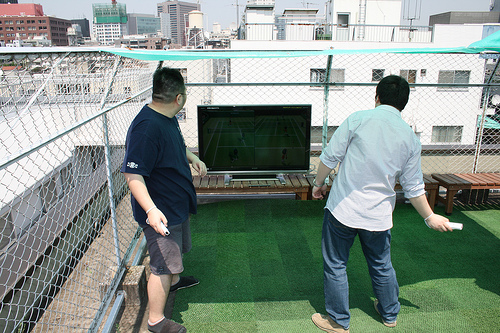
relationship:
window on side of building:
[310, 69, 350, 92] [125, 43, 498, 156]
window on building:
[434, 69, 473, 92] [125, 43, 498, 156]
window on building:
[310, 69, 350, 92] [125, 43, 498, 156]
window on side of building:
[216, 56, 230, 80] [125, 43, 498, 156]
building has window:
[125, 43, 498, 156] [310, 69, 350, 92]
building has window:
[125, 43, 498, 156] [216, 56, 230, 80]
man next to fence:
[117, 66, 213, 332] [15, 70, 163, 323]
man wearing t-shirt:
[117, 66, 213, 332] [129, 128, 199, 227]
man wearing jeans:
[316, 87, 453, 330] [322, 225, 404, 320]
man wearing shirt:
[316, 87, 453, 330] [334, 115, 426, 224]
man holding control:
[316, 87, 453, 330] [427, 217, 468, 236]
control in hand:
[427, 217, 468, 236] [432, 210, 451, 236]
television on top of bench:
[185, 99, 321, 176] [190, 172, 311, 202]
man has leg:
[117, 66, 213, 332] [146, 268, 177, 333]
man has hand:
[316, 87, 453, 330] [432, 210, 451, 236]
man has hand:
[117, 66, 213, 332] [145, 211, 177, 231]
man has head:
[117, 66, 213, 332] [146, 70, 193, 108]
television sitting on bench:
[185, 99, 321, 176] [175, 172, 325, 212]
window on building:
[430, 121, 470, 141] [125, 43, 498, 156]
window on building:
[216, 56, 230, 80] [125, 43, 498, 156]